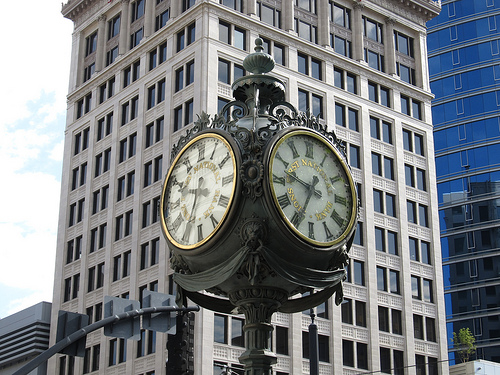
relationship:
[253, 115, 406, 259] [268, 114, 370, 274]
face outside clock